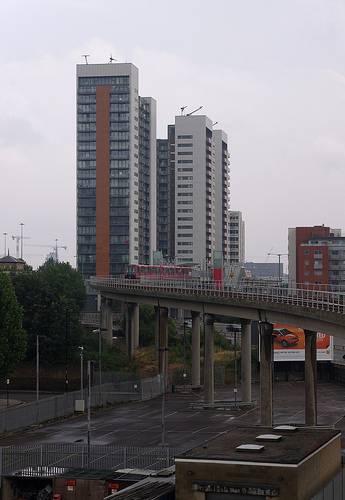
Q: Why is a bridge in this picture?
A: For the train tracks.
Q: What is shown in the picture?
A: A city.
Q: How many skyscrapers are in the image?
A: Four.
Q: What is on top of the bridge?
A: A train.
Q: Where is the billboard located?
A: Behind the bridge.